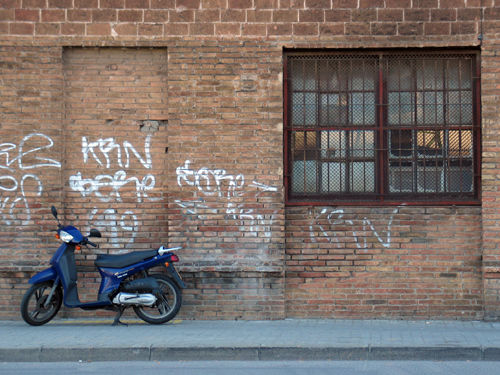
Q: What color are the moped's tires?
A: Black.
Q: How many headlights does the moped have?
A: One.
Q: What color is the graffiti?
A: White.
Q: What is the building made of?
A: Bricks.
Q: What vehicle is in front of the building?
A: A moped.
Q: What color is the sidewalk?
A: Grey.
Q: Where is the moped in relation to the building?
A: In front of it.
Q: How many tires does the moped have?
A: Two.